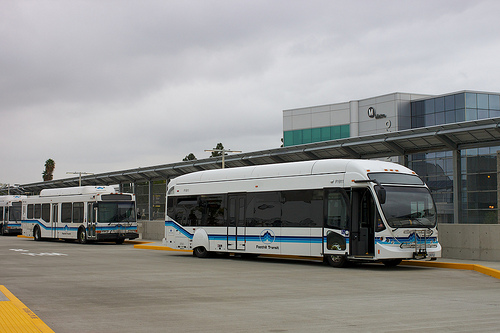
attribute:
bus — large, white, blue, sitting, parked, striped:
[174, 149, 411, 260]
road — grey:
[55, 234, 235, 311]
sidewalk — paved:
[142, 241, 164, 252]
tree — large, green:
[40, 157, 58, 178]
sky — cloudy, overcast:
[123, 27, 242, 150]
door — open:
[343, 190, 381, 264]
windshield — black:
[376, 185, 431, 236]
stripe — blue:
[191, 211, 346, 252]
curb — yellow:
[444, 256, 499, 281]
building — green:
[286, 91, 491, 147]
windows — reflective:
[415, 87, 500, 138]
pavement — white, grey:
[6, 244, 69, 260]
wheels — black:
[323, 229, 420, 267]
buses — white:
[2, 149, 446, 275]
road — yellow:
[0, 238, 69, 332]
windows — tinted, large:
[184, 190, 336, 238]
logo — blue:
[250, 222, 291, 259]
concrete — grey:
[206, 269, 459, 325]